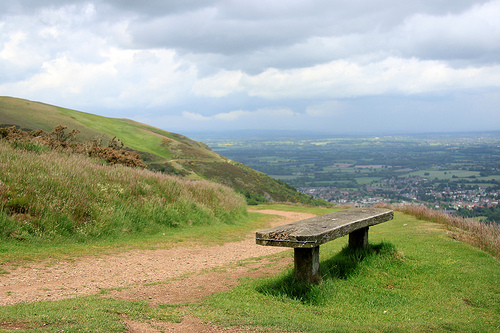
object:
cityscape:
[214, 135, 499, 210]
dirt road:
[0, 201, 325, 312]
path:
[0, 204, 255, 332]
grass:
[7, 97, 202, 167]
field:
[0, 200, 500, 333]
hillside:
[393, 200, 498, 263]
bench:
[255, 202, 393, 292]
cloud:
[235, 61, 500, 98]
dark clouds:
[88, 2, 416, 62]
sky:
[0, 23, 499, 96]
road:
[0, 201, 325, 309]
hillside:
[0, 120, 249, 252]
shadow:
[256, 237, 383, 304]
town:
[298, 135, 499, 209]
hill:
[0, 95, 498, 331]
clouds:
[24, 52, 177, 98]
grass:
[1, 141, 248, 234]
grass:
[331, 254, 499, 332]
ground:
[1, 207, 499, 331]